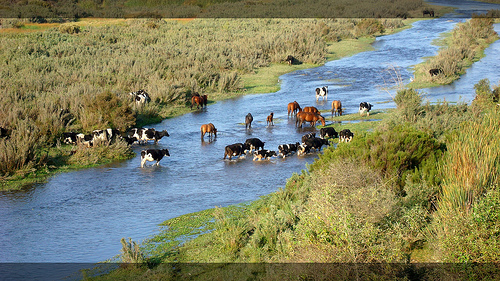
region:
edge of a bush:
[357, 197, 368, 219]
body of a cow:
[245, 150, 256, 168]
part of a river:
[183, 182, 197, 187]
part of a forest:
[59, 40, 80, 73]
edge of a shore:
[219, 209, 229, 211]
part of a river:
[203, 172, 219, 197]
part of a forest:
[401, 150, 417, 172]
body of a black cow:
[344, 102, 354, 117]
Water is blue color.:
[38, 196, 130, 241]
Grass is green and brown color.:
[307, 177, 464, 243]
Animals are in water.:
[120, 91, 335, 196]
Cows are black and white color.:
[85, 120, 250, 195]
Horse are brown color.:
[285, 90, 325, 122]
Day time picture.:
[10, 30, 485, 242]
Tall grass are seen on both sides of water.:
[40, 55, 415, 245]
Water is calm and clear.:
[32, 190, 182, 246]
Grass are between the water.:
[428, 27, 479, 80]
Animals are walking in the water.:
[136, 113, 298, 173]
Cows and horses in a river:
[30, 65, 435, 185]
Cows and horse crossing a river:
[29, 52, 399, 204]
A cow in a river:
[138, 138, 173, 172]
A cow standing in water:
[133, 143, 178, 175]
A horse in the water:
[197, 119, 221, 147]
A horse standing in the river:
[197, 121, 219, 146]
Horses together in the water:
[286, 98, 334, 134]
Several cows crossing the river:
[221, 121, 357, 166]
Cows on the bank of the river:
[16, 40, 178, 180]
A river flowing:
[11, 166, 145, 262]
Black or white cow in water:
[313, 82, 329, 100]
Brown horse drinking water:
[295, 112, 331, 127]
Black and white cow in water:
[140, 151, 174, 173]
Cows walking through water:
[226, 134, 347, 159]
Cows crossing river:
[118, 122, 171, 150]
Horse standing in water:
[193, 121, 222, 147]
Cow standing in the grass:
[127, 86, 151, 110]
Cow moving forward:
[313, 78, 334, 102]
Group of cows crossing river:
[224, 122, 354, 162]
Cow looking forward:
[135, 145, 179, 166]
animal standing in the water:
[194, 121, 221, 145]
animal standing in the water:
[237, 106, 259, 136]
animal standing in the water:
[184, 90, 214, 115]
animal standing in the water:
[137, 143, 173, 172]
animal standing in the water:
[135, 126, 172, 145]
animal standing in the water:
[217, 137, 252, 168]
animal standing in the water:
[282, 97, 303, 119]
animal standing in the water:
[262, 108, 281, 131]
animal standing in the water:
[305, 83, 339, 104]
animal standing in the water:
[353, 96, 377, 122]